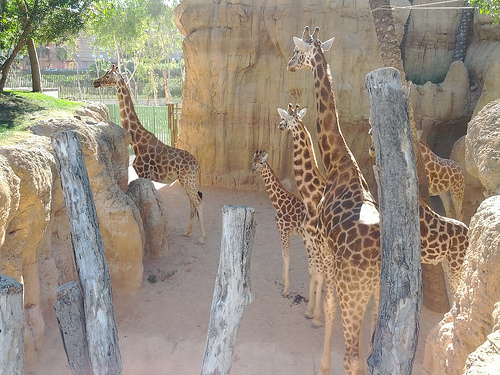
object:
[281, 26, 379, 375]
giraffe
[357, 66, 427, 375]
stump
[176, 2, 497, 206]
wall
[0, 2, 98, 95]
tree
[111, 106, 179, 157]
fence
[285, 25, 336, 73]
head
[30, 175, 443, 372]
ground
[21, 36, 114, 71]
building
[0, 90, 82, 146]
grass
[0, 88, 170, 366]
cliff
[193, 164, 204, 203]
tail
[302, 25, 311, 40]
horn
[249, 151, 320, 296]
baby